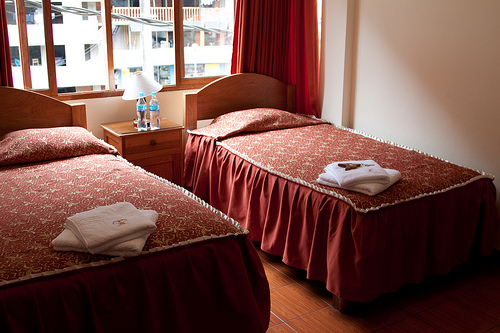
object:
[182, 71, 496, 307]
bed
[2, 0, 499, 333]
room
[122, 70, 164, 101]
shade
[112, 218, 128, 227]
emblem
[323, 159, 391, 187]
towel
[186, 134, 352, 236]
skirt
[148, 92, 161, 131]
bottles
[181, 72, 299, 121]
headboard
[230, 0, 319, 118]
drapes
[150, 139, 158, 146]
knob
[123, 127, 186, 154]
drawer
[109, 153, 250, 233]
trim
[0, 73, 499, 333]
two beds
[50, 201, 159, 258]
2 towels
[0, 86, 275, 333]
bed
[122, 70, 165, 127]
one lamp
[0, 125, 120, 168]
pillow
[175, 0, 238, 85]
windows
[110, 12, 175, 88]
building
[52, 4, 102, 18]
cables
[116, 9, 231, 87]
outside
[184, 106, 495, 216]
blanket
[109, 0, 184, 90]
window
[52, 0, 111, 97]
window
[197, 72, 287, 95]
arch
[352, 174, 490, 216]
ribbing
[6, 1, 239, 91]
view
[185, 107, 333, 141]
pillow case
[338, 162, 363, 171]
anchor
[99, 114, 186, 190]
night table